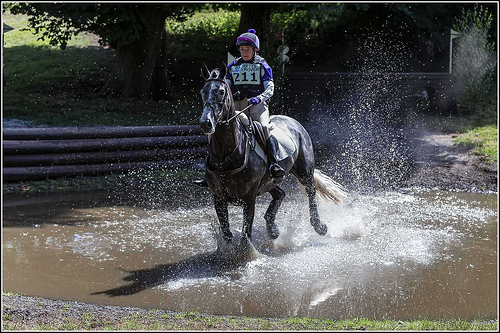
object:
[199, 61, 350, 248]
horse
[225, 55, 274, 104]
bib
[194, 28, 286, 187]
man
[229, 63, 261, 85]
contestant number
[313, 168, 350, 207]
tail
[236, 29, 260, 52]
bonnet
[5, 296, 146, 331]
stones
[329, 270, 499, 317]
mud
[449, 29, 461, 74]
flag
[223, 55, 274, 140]
riding outfit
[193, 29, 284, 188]
boy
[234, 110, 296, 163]
saddle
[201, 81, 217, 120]
mark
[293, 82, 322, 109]
wall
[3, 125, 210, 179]
fence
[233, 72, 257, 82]
211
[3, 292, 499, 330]
grass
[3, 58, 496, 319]
water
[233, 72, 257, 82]
lettering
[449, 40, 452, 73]
pole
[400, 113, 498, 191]
path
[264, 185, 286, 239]
leg